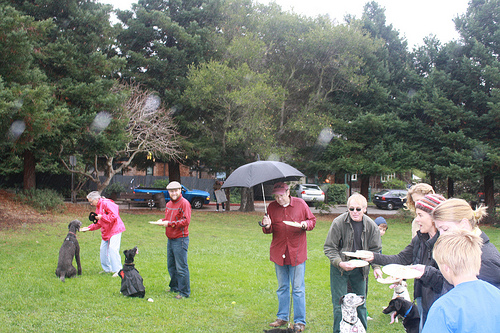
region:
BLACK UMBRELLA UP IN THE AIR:
[241, 162, 276, 174]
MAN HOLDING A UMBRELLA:
[262, 211, 268, 229]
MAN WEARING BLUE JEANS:
[293, 279, 299, 298]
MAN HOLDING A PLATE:
[283, 221, 303, 229]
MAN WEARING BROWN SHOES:
[272, 320, 306, 329]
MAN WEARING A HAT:
[167, 183, 184, 189]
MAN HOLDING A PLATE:
[145, 213, 174, 229]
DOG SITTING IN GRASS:
[57, 220, 81, 276]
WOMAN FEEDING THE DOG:
[76, 225, 91, 232]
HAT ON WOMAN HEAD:
[423, 194, 436, 210]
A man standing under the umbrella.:
[246, 160, 328, 316]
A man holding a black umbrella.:
[233, 135, 322, 306]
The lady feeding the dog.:
[43, 163, 135, 270]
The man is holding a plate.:
[138, 205, 221, 239]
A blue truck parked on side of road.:
[137, 168, 229, 210]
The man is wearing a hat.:
[158, 180, 190, 196]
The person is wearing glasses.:
[337, 200, 368, 216]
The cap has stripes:
[417, 191, 447, 208]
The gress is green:
[9, 255, 243, 308]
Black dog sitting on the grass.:
[113, 243, 148, 311]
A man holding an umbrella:
[217, 148, 322, 329]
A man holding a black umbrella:
[218, 141, 321, 326]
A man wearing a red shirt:
[222, 141, 317, 270]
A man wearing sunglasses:
[330, 187, 371, 224]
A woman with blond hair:
[428, 184, 488, 233]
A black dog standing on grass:
[119, 239, 153, 303]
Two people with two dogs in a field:
[52, 156, 205, 314]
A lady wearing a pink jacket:
[80, 182, 129, 244]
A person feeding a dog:
[42, 172, 122, 287]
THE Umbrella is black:
[209, 165, 292, 187]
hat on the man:
[166, 181, 177, 189]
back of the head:
[446, 240, 476, 276]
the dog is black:
[125, 248, 151, 296]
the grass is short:
[213, 238, 243, 280]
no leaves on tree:
[141, 131, 163, 148]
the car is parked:
[385, 187, 404, 207]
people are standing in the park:
[17, 173, 474, 322]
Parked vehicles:
[122, 170, 426, 220]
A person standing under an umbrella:
[211, 150, 317, 329]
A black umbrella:
[209, 143, 304, 221]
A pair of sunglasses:
[339, 200, 366, 215]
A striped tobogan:
[411, 192, 452, 214]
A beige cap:
[161, 182, 183, 189]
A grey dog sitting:
[51, 217, 86, 276]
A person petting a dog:
[51, 185, 126, 275]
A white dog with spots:
[334, 287, 366, 329]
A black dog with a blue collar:
[383, 295, 418, 332]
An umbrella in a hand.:
[219, 160, 304, 216]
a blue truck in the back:
[128, 178, 218, 213]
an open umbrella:
[220, 155, 306, 235]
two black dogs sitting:
[50, 217, 155, 299]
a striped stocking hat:
[410, 185, 445, 220]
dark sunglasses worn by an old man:
[345, 201, 362, 216]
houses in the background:
[40, 141, 421, 201]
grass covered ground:
[2, 192, 498, 332]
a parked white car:
[291, 178, 331, 207]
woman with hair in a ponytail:
[388, 199, 497, 327]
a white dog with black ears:
[332, 290, 372, 331]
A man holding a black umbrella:
[213, 152, 323, 329]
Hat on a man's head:
[160, 171, 190, 206]